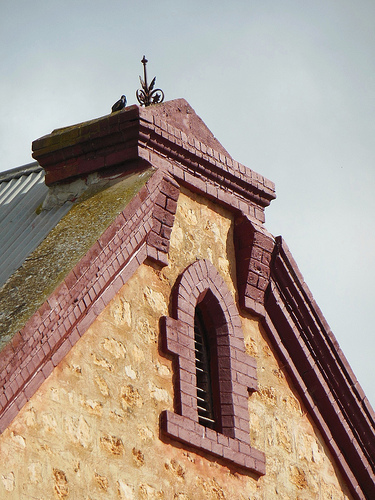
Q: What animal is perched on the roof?
A: Bird.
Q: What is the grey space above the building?
A: Sky.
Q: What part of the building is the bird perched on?
A: Roof.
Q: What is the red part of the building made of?
A: Brick.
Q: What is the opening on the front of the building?
A: Window.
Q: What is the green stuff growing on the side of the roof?
A: Moss.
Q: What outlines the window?
A: Bricks.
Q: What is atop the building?
A: Spire.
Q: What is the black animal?
A: Bird.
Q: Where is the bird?
A: On the roof.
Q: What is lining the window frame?
A: Bricks.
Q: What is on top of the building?
A: A spire.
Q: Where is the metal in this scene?
A: The roof.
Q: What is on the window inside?
A: Bars.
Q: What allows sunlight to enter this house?
A: The window.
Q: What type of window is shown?
A: An arched window.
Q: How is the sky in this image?
A: Gray.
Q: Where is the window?
A: On the front of a building.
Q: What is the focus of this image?
A: The top of a building.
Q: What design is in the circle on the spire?
A: A star.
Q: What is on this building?
A: A window.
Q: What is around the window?
A: Bricks.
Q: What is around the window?
A: Bricks.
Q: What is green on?
A: The roof.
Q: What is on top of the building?
A: Bricks.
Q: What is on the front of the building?
A: Bricks.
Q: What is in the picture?
A: A building.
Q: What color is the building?
A: Yellow and red.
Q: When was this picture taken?
A: Daytime.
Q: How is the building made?
A: Of stone and brick.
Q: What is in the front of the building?
A: A window.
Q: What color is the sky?
A: Light blue.